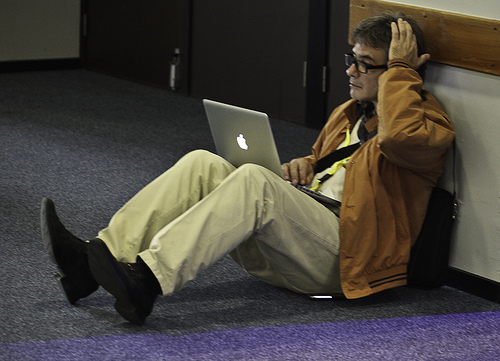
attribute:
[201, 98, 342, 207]
laptop — silver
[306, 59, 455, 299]
jacket — orange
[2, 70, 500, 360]
carpet — grey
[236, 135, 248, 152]
apple — lit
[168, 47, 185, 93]
doorstopper — silver